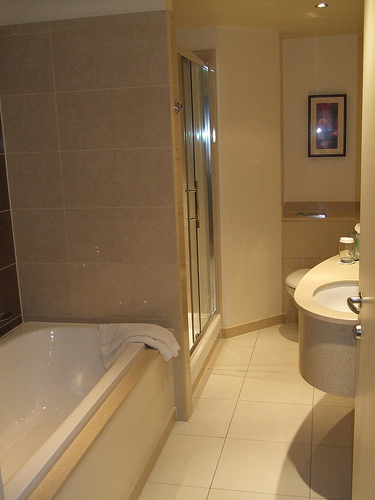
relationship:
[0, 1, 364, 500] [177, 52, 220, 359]
bathroom has shower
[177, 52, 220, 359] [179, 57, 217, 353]
shower has door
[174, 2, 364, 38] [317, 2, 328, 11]
ceiling has lighting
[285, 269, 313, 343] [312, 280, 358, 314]
toilet behind sink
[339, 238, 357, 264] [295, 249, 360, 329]
jar on counter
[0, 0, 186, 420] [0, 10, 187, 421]
wall has tile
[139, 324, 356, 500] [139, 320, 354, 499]
floor has tile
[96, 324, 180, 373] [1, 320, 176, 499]
towel on bathtub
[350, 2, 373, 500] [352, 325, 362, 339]
door has lock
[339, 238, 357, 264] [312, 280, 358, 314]
jar on sink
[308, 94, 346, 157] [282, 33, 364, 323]
picture on wall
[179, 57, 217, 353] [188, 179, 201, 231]
door has handle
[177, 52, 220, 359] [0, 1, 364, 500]
shower in bathroom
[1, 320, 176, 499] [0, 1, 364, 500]
bathtub in bathroom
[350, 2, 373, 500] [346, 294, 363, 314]
door has handle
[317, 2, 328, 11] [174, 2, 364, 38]
lighting in ceiling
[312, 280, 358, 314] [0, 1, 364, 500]
sink in bathroom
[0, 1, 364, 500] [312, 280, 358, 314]
bathroom has sink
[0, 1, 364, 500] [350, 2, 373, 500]
bathroom has door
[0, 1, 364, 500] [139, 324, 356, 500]
bathroom has floor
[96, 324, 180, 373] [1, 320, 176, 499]
mat over bathtub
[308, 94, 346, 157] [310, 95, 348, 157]
picture has frame